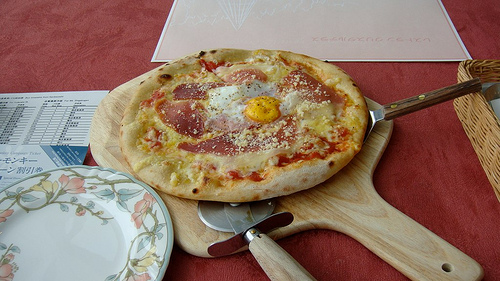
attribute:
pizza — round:
[120, 49, 369, 203]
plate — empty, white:
[6, 166, 173, 279]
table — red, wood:
[2, 2, 496, 278]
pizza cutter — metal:
[196, 196, 314, 277]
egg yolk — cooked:
[246, 93, 278, 124]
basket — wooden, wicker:
[452, 66, 500, 162]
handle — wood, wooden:
[250, 236, 311, 280]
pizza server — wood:
[355, 71, 485, 145]